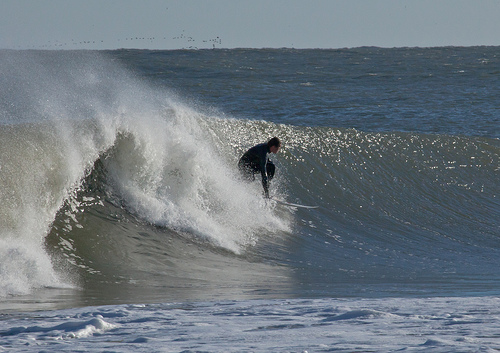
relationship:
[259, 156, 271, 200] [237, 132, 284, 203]
arm on man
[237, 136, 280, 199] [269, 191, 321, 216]
man on surfboard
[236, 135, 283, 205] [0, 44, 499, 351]
man surfing on water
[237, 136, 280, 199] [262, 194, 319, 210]
man leaning on board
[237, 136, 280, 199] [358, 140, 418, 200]
man in water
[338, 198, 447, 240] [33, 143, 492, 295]
ripples in water